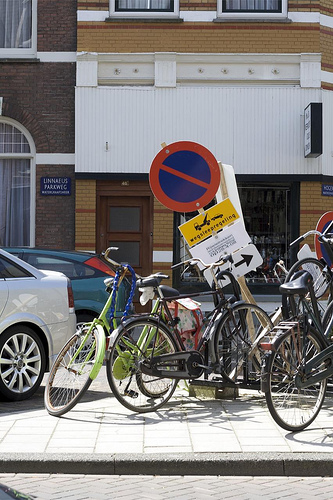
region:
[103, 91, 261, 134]
The top of the wall is white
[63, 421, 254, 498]
The street is made of cement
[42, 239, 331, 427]
The bike's are on the bike rack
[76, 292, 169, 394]
The color of the bike is green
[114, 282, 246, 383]
The color of the bike is black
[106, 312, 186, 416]
The back wheel of the tire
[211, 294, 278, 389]
The front wheel of the tire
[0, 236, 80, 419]
The white car is parked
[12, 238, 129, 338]
The green car is parked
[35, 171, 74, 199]
The sign on the wall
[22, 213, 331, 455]
Four bikes on bike rack.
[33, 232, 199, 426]
Neon green bike with wide seat.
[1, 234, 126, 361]
Teal car parked on street.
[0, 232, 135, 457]
White car parked near sidewalk.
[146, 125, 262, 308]
No parking sign on post by bikes.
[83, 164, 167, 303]
Door on building is brown.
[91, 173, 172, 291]
Door on building has two windows.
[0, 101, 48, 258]
Brick building has large arched window.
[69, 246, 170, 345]
Blue bike lock on green bike.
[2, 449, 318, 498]
Road is made of brick.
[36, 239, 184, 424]
blue and green bicycle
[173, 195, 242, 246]
yellow and black tow warning sign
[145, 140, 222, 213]
red and blue sign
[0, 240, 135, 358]
teal green car parked on street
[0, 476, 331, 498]
brown brick street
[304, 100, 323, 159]
black and white electrical sign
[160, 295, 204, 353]
multi-colored box behind bikes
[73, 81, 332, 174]
corrugated metal siding on building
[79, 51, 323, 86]
concrete building accent with flowers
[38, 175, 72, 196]
blue and white building sign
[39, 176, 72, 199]
Small white and blue sign on the brick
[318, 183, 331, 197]
Small white and blue sign on the brick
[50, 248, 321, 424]
Bicycles parked on the pavement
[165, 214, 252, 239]
Small yellow and black sign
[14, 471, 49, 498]
Small red brick pavement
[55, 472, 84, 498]
Small red brick pavement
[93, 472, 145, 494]
Small red brick pavement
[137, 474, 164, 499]
Small red brick pavement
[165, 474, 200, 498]
Small red brick pavement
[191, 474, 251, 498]
Small red brick pavement